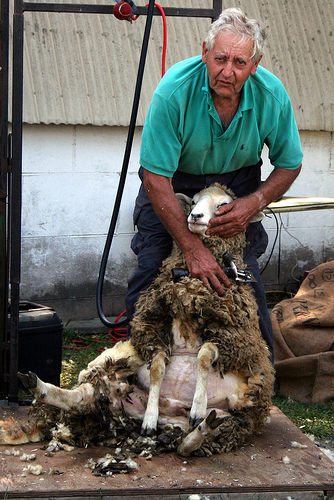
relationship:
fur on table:
[84, 449, 141, 476] [0, 391, 333, 498]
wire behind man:
[132, 2, 167, 79] [152, 8, 314, 205]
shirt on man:
[135, 51, 306, 179] [104, 13, 317, 257]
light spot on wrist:
[246, 187, 270, 214] [240, 190, 272, 217]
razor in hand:
[171, 252, 255, 283] [184, 248, 231, 296]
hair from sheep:
[0, 417, 145, 479] [153, 239, 269, 404]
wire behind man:
[133, 1, 168, 77] [123, 7, 301, 396]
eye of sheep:
[190, 199, 195, 204] [18, 182, 276, 457]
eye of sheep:
[218, 201, 228, 207] [18, 182, 276, 457]